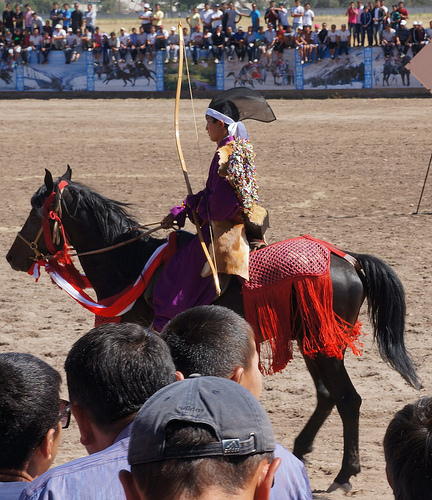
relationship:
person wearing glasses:
[0, 350, 71, 481] [59, 399, 72, 426]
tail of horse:
[356, 251, 425, 391] [5, 160, 422, 498]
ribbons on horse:
[30, 233, 176, 323] [5, 160, 422, 498]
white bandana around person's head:
[190, 96, 245, 136] [205, 92, 241, 143]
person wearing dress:
[160, 82, 278, 312] [149, 142, 276, 322]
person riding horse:
[169, 89, 273, 308] [5, 160, 422, 498]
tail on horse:
[356, 251, 425, 391] [5, 160, 422, 498]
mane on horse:
[71, 187, 136, 242] [1, 167, 403, 413]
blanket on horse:
[241, 236, 363, 376] [5, 160, 422, 498]